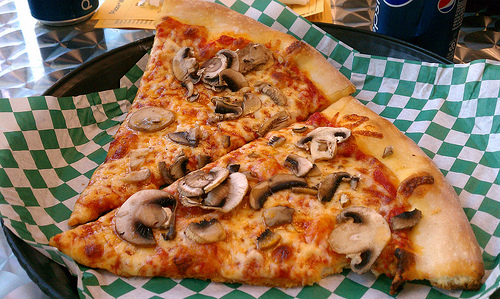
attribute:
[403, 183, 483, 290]
pizza crust — baked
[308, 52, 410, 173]
pizza crust — baked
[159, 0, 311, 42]
pizza crust — baked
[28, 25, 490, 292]
pizza — baked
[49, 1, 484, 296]
pizza — baked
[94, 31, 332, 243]
pizza — baked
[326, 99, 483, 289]
crust — brown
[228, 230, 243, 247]
cheese — Melted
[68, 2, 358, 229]
pizza — triangular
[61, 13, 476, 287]
pizzas — white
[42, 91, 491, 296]
pizza — baked, triangular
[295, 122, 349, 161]
mushroom — brown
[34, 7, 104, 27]
bottom — silver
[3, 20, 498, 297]
paper — green, white, checkered